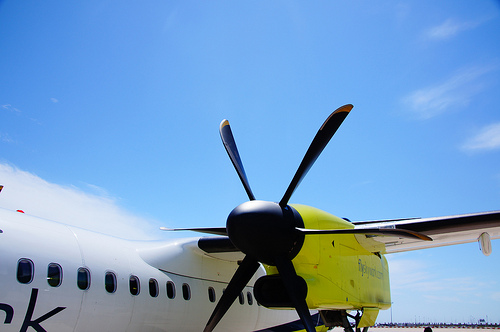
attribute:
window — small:
[41, 260, 69, 288]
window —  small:
[162, 277, 176, 297]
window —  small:
[180, 281, 192, 298]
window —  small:
[130, 274, 140, 294]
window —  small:
[105, 270, 116, 290]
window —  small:
[77, 266, 91, 288]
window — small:
[14, 255, 36, 289]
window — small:
[204, 283, 221, 307]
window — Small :
[144, 271, 173, 301]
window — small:
[76, 266, 91, 291]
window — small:
[103, 270, 116, 292]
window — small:
[128, 272, 140, 297]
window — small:
[149, 279, 158, 295]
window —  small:
[166, 280, 176, 299]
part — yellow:
[260, 202, 391, 307]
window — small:
[99, 265, 120, 300]